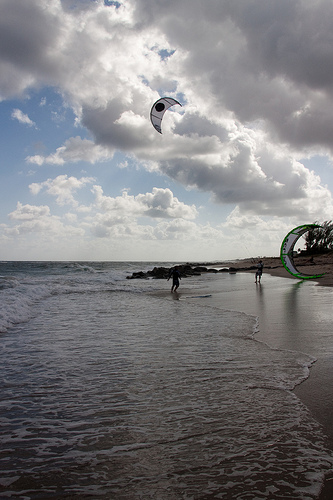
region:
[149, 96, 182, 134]
A kite in the sky.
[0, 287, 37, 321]
Part of a small wave.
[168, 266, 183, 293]
A person on the beach.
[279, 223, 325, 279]
A green and white kite.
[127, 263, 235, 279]
A pile of rocks.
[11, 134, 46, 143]
Part of the blue sky.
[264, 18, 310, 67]
Part of a grey cloud.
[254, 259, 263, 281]
A person flying a kite.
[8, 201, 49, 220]
A white cloud in the sky.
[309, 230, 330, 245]
Part of a tree.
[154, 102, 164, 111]
a black circle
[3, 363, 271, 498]
sea foam in the water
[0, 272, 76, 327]
some white beach waves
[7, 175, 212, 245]
some white puffy clouds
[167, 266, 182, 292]
a person on the beach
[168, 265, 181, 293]
a person standing in some water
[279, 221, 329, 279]
a green and white parasail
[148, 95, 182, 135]
a black and white parasail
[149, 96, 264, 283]
a man holding on to a parasail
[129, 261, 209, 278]
some sharp rocks in the ocean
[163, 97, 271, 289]
People on the beach flying kites.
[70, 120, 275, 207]
The sky is full of clouds.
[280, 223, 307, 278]
A kite on the sand.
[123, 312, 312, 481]
Water on the shoreline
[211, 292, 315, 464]
Water on the sand.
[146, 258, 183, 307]
Person playing in the water.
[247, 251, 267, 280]
A man flying a kite.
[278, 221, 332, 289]
The kite on the ground is green and white.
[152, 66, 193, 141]
The kite in the sky has a round circle on it.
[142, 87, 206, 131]
The kite is flying in the sky.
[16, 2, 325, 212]
the sky is partly cloudy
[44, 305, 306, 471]
the water is partly white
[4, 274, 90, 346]
the waves are white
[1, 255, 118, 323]
the waves are rolling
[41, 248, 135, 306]
the waves are in motion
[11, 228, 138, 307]
the water is splashing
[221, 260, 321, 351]
the sand is wet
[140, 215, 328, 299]
two people on the beach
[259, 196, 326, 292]
the kite is white and green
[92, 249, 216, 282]
rocks in the water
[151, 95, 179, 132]
a kite is on the air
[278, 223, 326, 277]
a kite is on the ground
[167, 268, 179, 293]
a man is at the shore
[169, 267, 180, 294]
the man is near the water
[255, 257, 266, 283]
a man is at the shoreline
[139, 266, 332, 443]
the water is coming in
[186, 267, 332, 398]
the shore line is wet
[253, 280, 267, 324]
a shadow is on the ground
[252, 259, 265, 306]
the man is casting a shadow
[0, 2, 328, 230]
the clouds are dark and grey